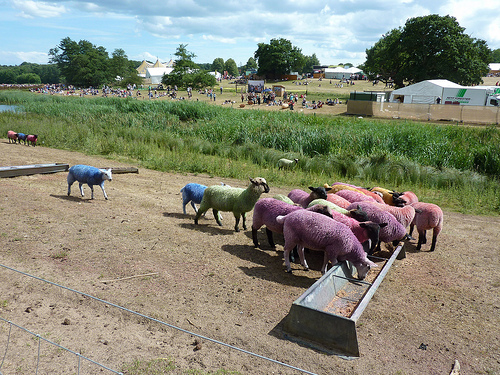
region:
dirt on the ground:
[62, 215, 147, 274]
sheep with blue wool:
[71, 162, 101, 190]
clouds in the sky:
[16, 5, 81, 30]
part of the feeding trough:
[300, 275, 382, 331]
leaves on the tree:
[392, 26, 463, 71]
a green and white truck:
[440, 86, 490, 104]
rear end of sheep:
[424, 205, 444, 225]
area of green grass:
[95, 120, 157, 155]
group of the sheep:
[175, 173, 455, 275]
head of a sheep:
[355, 254, 385, 284]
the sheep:
[39, 119, 137, 244]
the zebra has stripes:
[65, 144, 167, 274]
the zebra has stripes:
[36, 125, 243, 336]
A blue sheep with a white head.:
[65, 160, 117, 199]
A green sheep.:
[193, 180, 268, 232]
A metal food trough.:
[286, 230, 413, 357]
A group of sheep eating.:
[305, 166, 428, 264]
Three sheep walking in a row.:
[4, 124, 41, 151]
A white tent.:
[387, 78, 454, 103]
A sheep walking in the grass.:
[275, 154, 301, 172]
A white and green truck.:
[445, 85, 497, 109]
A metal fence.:
[5, 292, 311, 373]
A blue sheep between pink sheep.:
[17, 130, 27, 141]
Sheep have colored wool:
[148, 152, 463, 297]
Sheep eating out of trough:
[257, 198, 387, 284]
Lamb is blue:
[66, 156, 128, 218]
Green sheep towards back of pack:
[192, 178, 274, 236]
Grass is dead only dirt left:
[77, 206, 223, 308]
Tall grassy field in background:
[337, 122, 446, 183]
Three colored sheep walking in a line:
[2, 126, 51, 149]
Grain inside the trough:
[324, 286, 368, 314]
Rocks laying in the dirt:
[177, 324, 212, 359]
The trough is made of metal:
[292, 297, 362, 362]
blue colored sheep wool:
[66, 161, 110, 192]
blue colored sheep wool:
[59, 157, 119, 205]